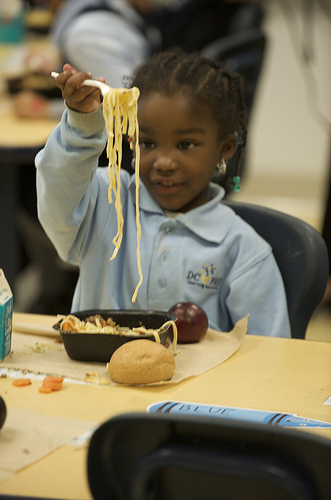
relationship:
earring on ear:
[214, 157, 227, 176] [218, 130, 240, 165]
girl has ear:
[32, 47, 292, 338] [218, 130, 240, 165]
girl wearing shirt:
[32, 47, 292, 338] [31, 97, 294, 333]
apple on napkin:
[165, 298, 209, 341] [171, 321, 246, 373]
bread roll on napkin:
[108, 339, 176, 385] [9, 342, 239, 389]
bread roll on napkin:
[108, 339, 176, 385] [1, 311, 252, 388]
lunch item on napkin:
[48, 304, 181, 358] [1, 311, 252, 388]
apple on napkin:
[168, 301, 209, 343] [1, 311, 252, 388]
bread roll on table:
[105, 335, 176, 387] [2, 309, 329, 495]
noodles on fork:
[103, 85, 144, 302] [48, 70, 138, 99]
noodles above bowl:
[103, 85, 144, 302] [51, 307, 176, 363]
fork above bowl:
[48, 70, 138, 99] [51, 307, 176, 363]